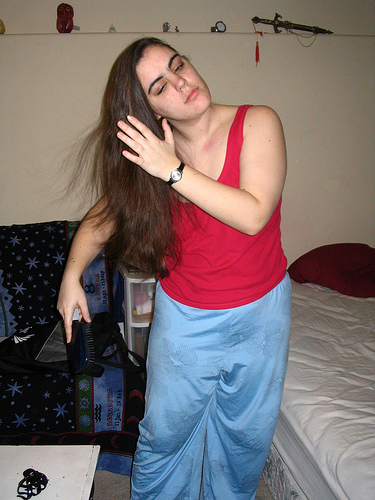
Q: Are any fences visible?
A: No, there are no fences.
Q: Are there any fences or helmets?
A: No, there are no fences or helmets.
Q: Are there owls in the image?
A: Yes, there is an owl.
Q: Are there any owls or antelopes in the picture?
A: Yes, there is an owl.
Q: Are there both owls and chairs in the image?
A: Yes, there are both an owl and a chair.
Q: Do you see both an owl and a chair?
A: Yes, there are both an owl and a chair.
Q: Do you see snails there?
A: No, there are no snails.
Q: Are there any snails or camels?
A: No, there are no snails or camels.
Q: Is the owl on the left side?
A: Yes, the owl is on the left of the image.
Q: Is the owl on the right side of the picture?
A: No, the owl is on the left of the image.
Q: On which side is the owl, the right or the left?
A: The owl is on the left of the image.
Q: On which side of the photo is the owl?
A: The owl is on the left of the image.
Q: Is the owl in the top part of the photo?
A: Yes, the owl is in the top of the image.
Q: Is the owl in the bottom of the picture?
A: No, the owl is in the top of the image.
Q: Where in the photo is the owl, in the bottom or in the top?
A: The owl is in the top of the image.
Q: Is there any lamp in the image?
A: No, there are no lamps.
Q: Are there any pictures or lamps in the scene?
A: No, there are no lamps or pictures.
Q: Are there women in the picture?
A: Yes, there is a woman.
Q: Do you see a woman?
A: Yes, there is a woman.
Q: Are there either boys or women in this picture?
A: Yes, there is a woman.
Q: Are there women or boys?
A: Yes, there is a woman.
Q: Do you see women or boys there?
A: Yes, there is a woman.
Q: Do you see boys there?
A: No, there are no boys.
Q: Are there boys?
A: No, there are no boys.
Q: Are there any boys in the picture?
A: No, there are no boys.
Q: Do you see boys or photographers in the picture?
A: No, there are no boys or photographers.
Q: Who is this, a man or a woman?
A: This is a woman.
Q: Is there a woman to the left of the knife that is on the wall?
A: Yes, there is a woman to the left of the knife.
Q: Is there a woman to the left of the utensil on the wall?
A: Yes, there is a woman to the left of the knife.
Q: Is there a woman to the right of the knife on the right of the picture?
A: No, the woman is to the left of the knife.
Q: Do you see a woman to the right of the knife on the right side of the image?
A: No, the woman is to the left of the knife.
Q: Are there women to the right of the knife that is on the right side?
A: No, the woman is to the left of the knife.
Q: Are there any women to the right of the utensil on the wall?
A: No, the woman is to the left of the knife.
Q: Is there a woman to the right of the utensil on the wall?
A: No, the woman is to the left of the knife.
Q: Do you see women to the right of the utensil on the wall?
A: No, the woman is to the left of the knife.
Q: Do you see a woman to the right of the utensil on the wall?
A: No, the woman is to the left of the knife.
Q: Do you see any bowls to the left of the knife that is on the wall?
A: No, there is a woman to the left of the knife.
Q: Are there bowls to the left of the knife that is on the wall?
A: No, there is a woman to the left of the knife.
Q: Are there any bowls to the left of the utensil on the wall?
A: No, there is a woman to the left of the knife.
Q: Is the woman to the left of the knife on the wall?
A: Yes, the woman is to the left of the knife.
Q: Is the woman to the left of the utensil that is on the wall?
A: Yes, the woman is to the left of the knife.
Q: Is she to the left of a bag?
A: No, the woman is to the left of the knife.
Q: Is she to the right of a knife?
A: No, the woman is to the left of a knife.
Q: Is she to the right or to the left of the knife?
A: The woman is to the left of the knife.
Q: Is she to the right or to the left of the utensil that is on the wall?
A: The woman is to the left of the knife.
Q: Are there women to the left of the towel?
A: No, the woman is to the right of the towel.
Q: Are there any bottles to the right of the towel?
A: No, there is a woman to the right of the towel.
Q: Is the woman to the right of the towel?
A: Yes, the woman is to the right of the towel.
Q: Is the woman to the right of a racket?
A: No, the woman is to the right of the towel.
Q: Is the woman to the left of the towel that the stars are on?
A: No, the woman is to the right of the towel.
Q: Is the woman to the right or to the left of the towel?
A: The woman is to the right of the towel.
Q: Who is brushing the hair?
A: The woman is brushing the hair.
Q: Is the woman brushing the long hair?
A: Yes, the woman is brushing the hair.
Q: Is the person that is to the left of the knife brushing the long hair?
A: Yes, the woman is brushing the hair.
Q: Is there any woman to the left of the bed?
A: Yes, there is a woman to the left of the bed.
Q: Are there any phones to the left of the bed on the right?
A: No, there is a woman to the left of the bed.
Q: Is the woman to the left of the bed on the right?
A: Yes, the woman is to the left of the bed.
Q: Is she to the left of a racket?
A: No, the woman is to the left of the bed.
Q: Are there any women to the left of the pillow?
A: Yes, there is a woman to the left of the pillow.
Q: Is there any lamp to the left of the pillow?
A: No, there is a woman to the left of the pillow.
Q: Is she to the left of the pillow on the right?
A: Yes, the woman is to the left of the pillow.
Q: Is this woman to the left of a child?
A: No, the woman is to the left of the pillow.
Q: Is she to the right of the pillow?
A: No, the woman is to the left of the pillow.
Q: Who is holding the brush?
A: The woman is holding the brush.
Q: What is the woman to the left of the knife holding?
A: The woman is holding the brush.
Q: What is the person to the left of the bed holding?
A: The woman is holding the brush.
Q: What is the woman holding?
A: The woman is holding the brush.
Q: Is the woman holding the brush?
A: Yes, the woman is holding the brush.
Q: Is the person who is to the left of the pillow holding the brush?
A: Yes, the woman is holding the brush.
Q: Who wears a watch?
A: The woman wears a watch.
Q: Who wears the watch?
A: The woman wears a watch.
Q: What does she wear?
A: The woman wears a watch.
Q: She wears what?
A: The woman wears a watch.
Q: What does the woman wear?
A: The woman wears a watch.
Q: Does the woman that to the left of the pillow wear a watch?
A: Yes, the woman wears a watch.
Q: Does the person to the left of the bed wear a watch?
A: Yes, the woman wears a watch.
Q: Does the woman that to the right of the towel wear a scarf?
A: No, the woman wears a watch.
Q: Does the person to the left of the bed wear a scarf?
A: No, the woman wears a watch.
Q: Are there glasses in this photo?
A: No, there are no glasses.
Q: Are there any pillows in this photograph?
A: Yes, there is a pillow.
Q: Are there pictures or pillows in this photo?
A: Yes, there is a pillow.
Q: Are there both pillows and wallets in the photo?
A: No, there is a pillow but no wallets.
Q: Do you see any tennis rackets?
A: No, there are no tennis rackets.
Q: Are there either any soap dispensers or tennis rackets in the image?
A: No, there are no tennis rackets or soap dispensers.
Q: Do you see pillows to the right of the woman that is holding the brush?
A: Yes, there is a pillow to the right of the woman.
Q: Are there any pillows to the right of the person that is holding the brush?
A: Yes, there is a pillow to the right of the woman.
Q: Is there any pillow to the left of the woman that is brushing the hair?
A: No, the pillow is to the right of the woman.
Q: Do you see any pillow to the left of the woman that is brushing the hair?
A: No, the pillow is to the right of the woman.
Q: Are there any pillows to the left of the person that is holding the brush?
A: No, the pillow is to the right of the woman.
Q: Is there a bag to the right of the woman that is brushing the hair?
A: No, there is a pillow to the right of the woman.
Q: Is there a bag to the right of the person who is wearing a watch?
A: No, there is a pillow to the right of the woman.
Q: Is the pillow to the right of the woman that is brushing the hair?
A: Yes, the pillow is to the right of the woman.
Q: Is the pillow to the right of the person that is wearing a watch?
A: Yes, the pillow is to the right of the woman.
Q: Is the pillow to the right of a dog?
A: No, the pillow is to the right of the woman.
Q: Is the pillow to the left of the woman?
A: No, the pillow is to the right of the woman.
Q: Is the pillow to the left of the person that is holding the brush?
A: No, the pillow is to the right of the woman.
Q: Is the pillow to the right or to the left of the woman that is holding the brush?
A: The pillow is to the right of the woman.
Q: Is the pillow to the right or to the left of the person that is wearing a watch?
A: The pillow is to the right of the woman.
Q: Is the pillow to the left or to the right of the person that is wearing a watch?
A: The pillow is to the right of the woman.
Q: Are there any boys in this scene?
A: No, there are no boys.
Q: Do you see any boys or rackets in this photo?
A: No, there are no boys or rackets.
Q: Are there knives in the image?
A: Yes, there is a knife.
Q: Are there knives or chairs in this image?
A: Yes, there is a knife.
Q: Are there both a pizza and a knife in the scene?
A: No, there is a knife but no pizzas.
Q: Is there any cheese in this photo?
A: No, there is no cheese.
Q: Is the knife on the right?
A: Yes, the knife is on the right of the image.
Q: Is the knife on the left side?
A: No, the knife is on the right of the image.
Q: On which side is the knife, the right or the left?
A: The knife is on the right of the image.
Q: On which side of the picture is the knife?
A: The knife is on the right of the image.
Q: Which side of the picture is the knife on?
A: The knife is on the right of the image.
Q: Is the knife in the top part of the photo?
A: Yes, the knife is in the top of the image.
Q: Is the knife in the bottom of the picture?
A: No, the knife is in the top of the image.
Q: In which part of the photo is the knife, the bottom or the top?
A: The knife is in the top of the image.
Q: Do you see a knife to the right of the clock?
A: Yes, there is a knife to the right of the clock.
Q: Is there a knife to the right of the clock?
A: Yes, there is a knife to the right of the clock.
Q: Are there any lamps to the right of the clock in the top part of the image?
A: No, there is a knife to the right of the clock.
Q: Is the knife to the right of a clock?
A: Yes, the knife is to the right of a clock.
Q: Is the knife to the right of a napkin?
A: No, the knife is to the right of a clock.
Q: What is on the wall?
A: The knife is on the wall.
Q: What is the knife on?
A: The knife is on the wall.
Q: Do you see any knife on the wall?
A: Yes, there is a knife on the wall.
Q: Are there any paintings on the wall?
A: No, there is a knife on the wall.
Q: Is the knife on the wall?
A: Yes, the knife is on the wall.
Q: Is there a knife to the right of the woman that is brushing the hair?
A: Yes, there is a knife to the right of the woman.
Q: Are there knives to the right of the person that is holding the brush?
A: Yes, there is a knife to the right of the woman.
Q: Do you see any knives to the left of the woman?
A: No, the knife is to the right of the woman.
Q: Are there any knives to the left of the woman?
A: No, the knife is to the right of the woman.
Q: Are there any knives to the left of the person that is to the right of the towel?
A: No, the knife is to the right of the woman.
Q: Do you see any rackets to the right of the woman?
A: No, there is a knife to the right of the woman.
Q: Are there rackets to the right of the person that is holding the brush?
A: No, there is a knife to the right of the woman.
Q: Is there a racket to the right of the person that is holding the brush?
A: No, there is a knife to the right of the woman.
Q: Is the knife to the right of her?
A: Yes, the knife is to the right of a woman.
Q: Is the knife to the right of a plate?
A: No, the knife is to the right of a woman.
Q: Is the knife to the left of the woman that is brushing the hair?
A: No, the knife is to the right of the woman.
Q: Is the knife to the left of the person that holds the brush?
A: No, the knife is to the right of the woman.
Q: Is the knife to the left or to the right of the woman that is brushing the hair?
A: The knife is to the right of the woman.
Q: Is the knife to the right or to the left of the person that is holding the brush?
A: The knife is to the right of the woman.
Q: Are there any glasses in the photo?
A: No, there are no glasses.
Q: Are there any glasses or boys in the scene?
A: No, there are no glasses or boys.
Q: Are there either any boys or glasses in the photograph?
A: No, there are no glasses or boys.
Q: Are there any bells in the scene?
A: No, there are no bells.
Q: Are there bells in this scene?
A: No, there are no bells.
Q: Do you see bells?
A: No, there are no bells.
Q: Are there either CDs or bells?
A: No, there are no bells or cds.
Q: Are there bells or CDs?
A: No, there are no bells or cds.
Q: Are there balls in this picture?
A: No, there are no balls.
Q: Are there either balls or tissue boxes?
A: No, there are no balls or tissue boxes.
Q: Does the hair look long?
A: Yes, the hair is long.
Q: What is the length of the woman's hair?
A: The hair is long.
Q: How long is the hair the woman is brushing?
A: The hair is long.